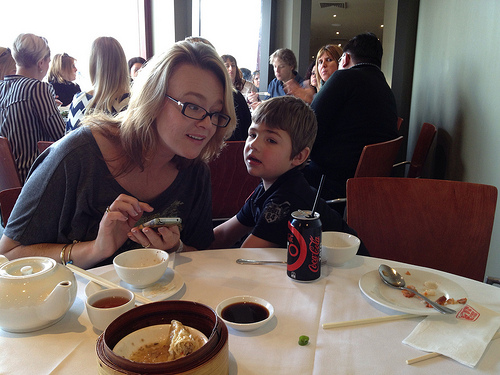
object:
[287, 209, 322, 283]
can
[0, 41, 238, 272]
person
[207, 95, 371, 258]
person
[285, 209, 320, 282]
soda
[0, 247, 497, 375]
table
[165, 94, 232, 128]
glasses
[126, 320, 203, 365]
food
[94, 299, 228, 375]
dish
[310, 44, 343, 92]
woman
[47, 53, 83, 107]
woman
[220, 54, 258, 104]
woman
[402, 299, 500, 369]
napkin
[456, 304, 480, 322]
writing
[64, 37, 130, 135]
person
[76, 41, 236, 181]
hair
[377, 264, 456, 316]
spoon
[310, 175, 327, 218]
straw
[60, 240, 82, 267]
bracelet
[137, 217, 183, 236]
cell phone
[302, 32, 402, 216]
person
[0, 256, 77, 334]
tea kettle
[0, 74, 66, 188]
shirt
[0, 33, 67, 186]
woman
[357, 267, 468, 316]
plate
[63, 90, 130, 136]
shirt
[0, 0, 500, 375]
restaurant